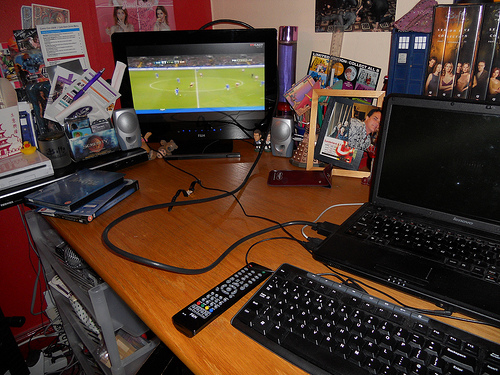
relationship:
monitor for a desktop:
[110, 26, 277, 145] [39, 157, 230, 374]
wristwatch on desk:
[167, 178, 202, 210] [39, 157, 230, 374]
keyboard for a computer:
[232, 263, 499, 375] [112, 24, 277, 160]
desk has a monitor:
[39, 157, 230, 374] [112, 24, 277, 160]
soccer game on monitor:
[128, 46, 264, 112] [112, 24, 277, 160]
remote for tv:
[172, 262, 271, 338] [112, 24, 277, 160]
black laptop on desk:
[310, 93, 499, 324] [39, 157, 230, 374]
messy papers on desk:
[21, 2, 126, 123] [39, 157, 230, 374]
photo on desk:
[307, 84, 386, 176] [39, 157, 230, 374]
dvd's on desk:
[24, 171, 138, 221] [39, 157, 230, 374]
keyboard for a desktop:
[232, 263, 499, 375] [112, 24, 277, 160]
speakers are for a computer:
[270, 115, 294, 161] [112, 24, 277, 160]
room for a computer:
[0, 1, 499, 375] [112, 24, 277, 160]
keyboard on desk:
[232, 263, 499, 375] [39, 157, 230, 374]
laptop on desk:
[310, 93, 499, 324] [39, 157, 230, 374]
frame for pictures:
[307, 84, 386, 176] [312, 96, 381, 172]